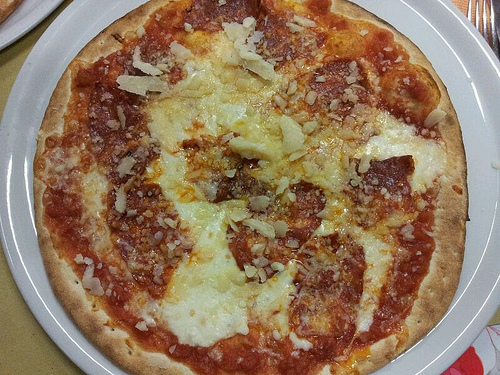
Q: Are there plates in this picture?
A: Yes, there is a plate.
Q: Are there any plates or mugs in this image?
A: Yes, there is a plate.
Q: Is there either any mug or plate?
A: Yes, there is a plate.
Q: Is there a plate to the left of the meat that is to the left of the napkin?
A: Yes, there is a plate to the left of the meat.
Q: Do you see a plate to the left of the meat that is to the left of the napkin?
A: Yes, there is a plate to the left of the meat.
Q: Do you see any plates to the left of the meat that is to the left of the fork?
A: Yes, there is a plate to the left of the meat.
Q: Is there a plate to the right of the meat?
A: No, the plate is to the left of the meat.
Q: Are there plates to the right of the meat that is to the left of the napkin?
A: No, the plate is to the left of the meat.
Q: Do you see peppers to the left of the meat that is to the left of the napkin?
A: No, there is a plate to the left of the meat.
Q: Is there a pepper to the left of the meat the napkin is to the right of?
A: No, there is a plate to the left of the meat.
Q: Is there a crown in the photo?
A: No, there are no crowns.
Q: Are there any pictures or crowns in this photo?
A: No, there are no crowns or pictures.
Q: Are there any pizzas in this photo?
A: Yes, there is a pizza.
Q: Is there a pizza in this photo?
A: Yes, there is a pizza.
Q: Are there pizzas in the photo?
A: Yes, there is a pizza.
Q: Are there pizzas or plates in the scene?
A: Yes, there is a pizza.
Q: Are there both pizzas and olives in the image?
A: No, there is a pizza but no olives.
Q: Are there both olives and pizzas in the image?
A: No, there is a pizza but no olives.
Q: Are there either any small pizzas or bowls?
A: Yes, there is a small pizza.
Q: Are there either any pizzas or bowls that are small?
A: Yes, the pizza is small.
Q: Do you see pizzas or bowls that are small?
A: Yes, the pizza is small.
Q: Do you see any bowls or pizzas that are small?
A: Yes, the pizza is small.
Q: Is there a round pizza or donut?
A: Yes, there is a round pizza.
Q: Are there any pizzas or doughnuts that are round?
A: Yes, the pizza is round.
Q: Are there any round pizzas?
A: Yes, there is a round pizza.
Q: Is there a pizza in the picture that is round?
A: Yes, there is a pizza that is round.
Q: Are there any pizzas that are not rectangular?
A: Yes, there is a round pizza.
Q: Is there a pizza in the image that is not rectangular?
A: Yes, there is a round pizza.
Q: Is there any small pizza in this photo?
A: Yes, there is a small pizza.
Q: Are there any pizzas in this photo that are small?
A: Yes, there is a pizza that is small.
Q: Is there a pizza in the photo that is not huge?
A: Yes, there is a small pizza.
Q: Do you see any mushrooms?
A: No, there are no mushrooms.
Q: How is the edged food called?
A: The food is a pizza.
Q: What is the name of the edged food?
A: The food is a pizza.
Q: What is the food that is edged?
A: The food is a pizza.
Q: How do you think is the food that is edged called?
A: The food is a pizza.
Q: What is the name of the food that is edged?
A: The food is a pizza.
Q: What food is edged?
A: The food is a pizza.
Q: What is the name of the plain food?
A: The food is a pizza.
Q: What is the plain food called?
A: The food is a pizza.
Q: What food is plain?
A: The food is a pizza.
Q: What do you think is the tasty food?
A: The food is a pizza.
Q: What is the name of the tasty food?
A: The food is a pizza.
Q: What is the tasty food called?
A: The food is a pizza.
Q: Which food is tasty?
A: The food is a pizza.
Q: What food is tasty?
A: The food is a pizza.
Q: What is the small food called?
A: The food is a pizza.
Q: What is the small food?
A: The food is a pizza.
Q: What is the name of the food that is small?
A: The food is a pizza.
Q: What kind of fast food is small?
A: The fast food is a pizza.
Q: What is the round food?
A: The food is a pizza.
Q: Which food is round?
A: The food is a pizza.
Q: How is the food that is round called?
A: The food is a pizza.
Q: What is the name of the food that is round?
A: The food is a pizza.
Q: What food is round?
A: The food is a pizza.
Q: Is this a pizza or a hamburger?
A: This is a pizza.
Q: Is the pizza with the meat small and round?
A: Yes, the pizza is small and round.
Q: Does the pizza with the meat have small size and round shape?
A: Yes, the pizza is small and round.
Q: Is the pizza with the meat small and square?
A: No, the pizza is small but round.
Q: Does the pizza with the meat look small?
A: Yes, the pizza is small.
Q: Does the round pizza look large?
A: No, the pizza is small.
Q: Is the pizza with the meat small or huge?
A: The pizza is small.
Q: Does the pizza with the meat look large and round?
A: No, the pizza is round but small.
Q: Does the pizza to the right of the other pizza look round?
A: Yes, the pizza is round.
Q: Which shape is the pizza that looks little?
A: The pizza is round.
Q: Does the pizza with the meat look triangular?
A: No, the pizza is round.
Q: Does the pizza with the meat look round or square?
A: The pizza is round.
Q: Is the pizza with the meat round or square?
A: The pizza is round.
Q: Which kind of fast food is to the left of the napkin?
A: The food is a pizza.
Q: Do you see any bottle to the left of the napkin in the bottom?
A: No, there is a pizza to the left of the napkin.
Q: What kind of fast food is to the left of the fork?
A: The food is a pizza.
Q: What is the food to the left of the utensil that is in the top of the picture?
A: The food is a pizza.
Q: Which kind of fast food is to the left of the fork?
A: The food is a pizza.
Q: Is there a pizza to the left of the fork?
A: Yes, there is a pizza to the left of the fork.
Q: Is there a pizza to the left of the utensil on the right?
A: Yes, there is a pizza to the left of the fork.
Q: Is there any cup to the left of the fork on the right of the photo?
A: No, there is a pizza to the left of the fork.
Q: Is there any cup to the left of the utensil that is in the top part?
A: No, there is a pizza to the left of the fork.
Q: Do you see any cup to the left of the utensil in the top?
A: No, there is a pizza to the left of the fork.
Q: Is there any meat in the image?
A: Yes, there is meat.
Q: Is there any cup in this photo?
A: No, there are no cups.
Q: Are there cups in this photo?
A: No, there are no cups.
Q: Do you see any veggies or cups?
A: No, there are no cups or veggies.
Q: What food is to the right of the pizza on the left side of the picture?
A: The food is meat.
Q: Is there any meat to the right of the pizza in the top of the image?
A: Yes, there is meat to the right of the pizza.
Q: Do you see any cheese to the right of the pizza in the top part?
A: No, there is meat to the right of the pizza.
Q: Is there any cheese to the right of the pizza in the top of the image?
A: No, there is meat to the right of the pizza.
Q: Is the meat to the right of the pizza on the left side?
A: Yes, the meat is to the right of the pizza.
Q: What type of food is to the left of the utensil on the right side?
A: The food is meat.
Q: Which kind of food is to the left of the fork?
A: The food is meat.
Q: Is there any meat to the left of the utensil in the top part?
A: Yes, there is meat to the left of the fork.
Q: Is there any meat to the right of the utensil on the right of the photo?
A: No, the meat is to the left of the fork.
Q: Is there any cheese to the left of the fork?
A: No, there is meat to the left of the fork.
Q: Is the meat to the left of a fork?
A: Yes, the meat is to the left of a fork.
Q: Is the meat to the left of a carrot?
A: No, the meat is to the left of a fork.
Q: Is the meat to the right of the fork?
A: No, the meat is to the left of the fork.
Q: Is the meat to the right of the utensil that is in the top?
A: No, the meat is to the left of the fork.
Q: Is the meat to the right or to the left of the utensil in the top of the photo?
A: The meat is to the left of the fork.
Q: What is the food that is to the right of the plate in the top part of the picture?
A: The food is meat.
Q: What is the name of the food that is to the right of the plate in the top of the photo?
A: The food is meat.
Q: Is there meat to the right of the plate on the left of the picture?
A: Yes, there is meat to the right of the plate.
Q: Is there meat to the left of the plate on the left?
A: No, the meat is to the right of the plate.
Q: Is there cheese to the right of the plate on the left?
A: No, there is meat to the right of the plate.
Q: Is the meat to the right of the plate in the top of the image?
A: Yes, the meat is to the right of the plate.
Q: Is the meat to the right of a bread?
A: No, the meat is to the right of the plate.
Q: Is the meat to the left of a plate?
A: No, the meat is to the right of a plate.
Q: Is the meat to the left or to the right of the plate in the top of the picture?
A: The meat is to the right of the plate.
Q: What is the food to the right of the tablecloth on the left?
A: The food is meat.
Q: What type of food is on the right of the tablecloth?
A: The food is meat.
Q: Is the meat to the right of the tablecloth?
A: Yes, the meat is to the right of the tablecloth.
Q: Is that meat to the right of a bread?
A: No, the meat is to the right of the tablecloth.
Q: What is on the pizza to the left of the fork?
A: The meat is on the pizza.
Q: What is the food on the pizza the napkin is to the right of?
A: The food is meat.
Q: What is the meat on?
A: The meat is on the pizza.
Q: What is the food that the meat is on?
A: The food is a pizza.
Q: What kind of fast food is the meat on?
A: The meat is on the pizza.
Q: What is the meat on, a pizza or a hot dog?
A: The meat is on a pizza.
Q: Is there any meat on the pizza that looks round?
A: Yes, there is meat on the pizza.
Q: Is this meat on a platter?
A: No, the meat is on the pizza.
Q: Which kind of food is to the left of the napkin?
A: The food is meat.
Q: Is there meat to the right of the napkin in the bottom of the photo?
A: No, the meat is to the left of the napkin.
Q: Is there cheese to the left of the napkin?
A: No, there is meat to the left of the napkin.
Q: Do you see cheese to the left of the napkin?
A: No, there is meat to the left of the napkin.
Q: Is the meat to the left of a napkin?
A: Yes, the meat is to the left of a napkin.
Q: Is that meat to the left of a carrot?
A: No, the meat is to the left of a napkin.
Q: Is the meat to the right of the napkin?
A: No, the meat is to the left of the napkin.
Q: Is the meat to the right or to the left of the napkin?
A: The meat is to the left of the napkin.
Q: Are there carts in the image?
A: No, there are no carts.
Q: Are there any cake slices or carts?
A: No, there are no carts or cake slices.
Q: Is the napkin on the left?
A: No, the napkin is on the right of the image.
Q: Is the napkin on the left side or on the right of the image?
A: The napkin is on the right of the image.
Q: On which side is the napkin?
A: The napkin is on the right of the image.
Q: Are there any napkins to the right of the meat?
A: Yes, there is a napkin to the right of the meat.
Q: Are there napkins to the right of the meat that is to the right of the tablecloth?
A: Yes, there is a napkin to the right of the meat.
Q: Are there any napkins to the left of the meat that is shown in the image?
A: No, the napkin is to the right of the meat.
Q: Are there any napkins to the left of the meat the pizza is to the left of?
A: No, the napkin is to the right of the meat.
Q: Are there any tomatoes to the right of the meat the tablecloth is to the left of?
A: No, there is a napkin to the right of the meat.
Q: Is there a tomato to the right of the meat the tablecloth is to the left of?
A: No, there is a napkin to the right of the meat.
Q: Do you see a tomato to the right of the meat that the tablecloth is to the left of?
A: No, there is a napkin to the right of the meat.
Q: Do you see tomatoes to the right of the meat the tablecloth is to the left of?
A: No, there is a napkin to the right of the meat.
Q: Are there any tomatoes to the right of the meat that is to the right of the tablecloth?
A: No, there is a napkin to the right of the meat.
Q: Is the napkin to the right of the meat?
A: Yes, the napkin is to the right of the meat.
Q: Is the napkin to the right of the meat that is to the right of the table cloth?
A: Yes, the napkin is to the right of the meat.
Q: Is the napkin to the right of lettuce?
A: No, the napkin is to the right of the meat.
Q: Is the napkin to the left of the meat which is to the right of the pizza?
A: No, the napkin is to the right of the meat.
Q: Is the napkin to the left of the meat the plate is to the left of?
A: No, the napkin is to the right of the meat.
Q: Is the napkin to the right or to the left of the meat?
A: The napkin is to the right of the meat.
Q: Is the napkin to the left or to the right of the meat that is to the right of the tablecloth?
A: The napkin is to the right of the meat.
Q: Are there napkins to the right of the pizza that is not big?
A: Yes, there is a napkin to the right of the pizza.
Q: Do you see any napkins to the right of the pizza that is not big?
A: Yes, there is a napkin to the right of the pizza.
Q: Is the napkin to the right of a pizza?
A: Yes, the napkin is to the right of a pizza.